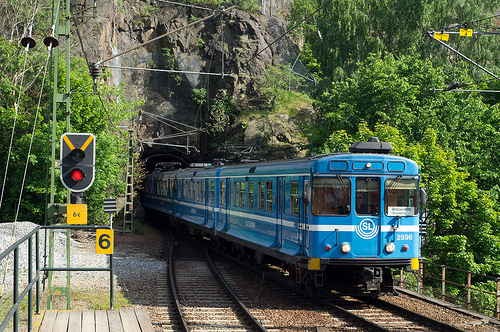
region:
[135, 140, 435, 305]
blue train on train tracks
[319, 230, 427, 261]
headlights on front of train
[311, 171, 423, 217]
windshield on front of train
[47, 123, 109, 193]
train traffic light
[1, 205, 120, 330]
metal fence on side of train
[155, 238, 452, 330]
two sets of train tracks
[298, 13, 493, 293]
trees bordering train tracks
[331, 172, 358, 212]
windshield wipers on front of train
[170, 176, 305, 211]
windows on side of train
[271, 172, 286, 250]
doors on side of train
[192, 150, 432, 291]
A blue train in movement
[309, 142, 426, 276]
The front of a train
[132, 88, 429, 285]
Train is coming out of a cave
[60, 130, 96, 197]
Red light on a sign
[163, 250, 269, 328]
Railroad trackson the ground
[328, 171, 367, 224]
Windshield wipers on the front of a train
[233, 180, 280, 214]
Windows on the side of a train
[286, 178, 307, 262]
Door of a blue train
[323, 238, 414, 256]
Lights on the front of a train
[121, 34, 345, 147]
Big mountain with foliage on it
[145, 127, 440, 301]
the train is blue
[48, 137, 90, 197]
the light is red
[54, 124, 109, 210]
the light is red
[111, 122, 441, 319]
A blue train coming out of a tunnel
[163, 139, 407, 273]
blue and white train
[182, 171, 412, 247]
white stripe on train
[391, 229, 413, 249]
white number on train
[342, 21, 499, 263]
green trees near train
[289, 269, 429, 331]
train on brown track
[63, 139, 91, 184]
red light on post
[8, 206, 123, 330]
green rails on fence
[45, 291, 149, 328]
brown and wooden planks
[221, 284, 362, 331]
brown gravel between tracks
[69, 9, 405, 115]
power lines over train